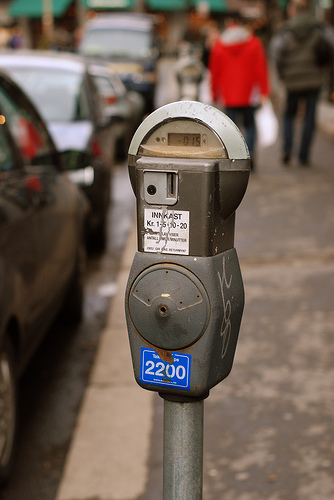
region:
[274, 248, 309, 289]
part of a walkpath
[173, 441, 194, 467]
part of a post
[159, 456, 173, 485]
edge of a post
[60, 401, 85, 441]
edge of a road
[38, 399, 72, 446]
part of a road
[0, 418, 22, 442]
part of a rim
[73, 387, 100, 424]
edge of a line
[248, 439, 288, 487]
part of a walkpath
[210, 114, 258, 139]
part of a metal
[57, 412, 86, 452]
edge of a line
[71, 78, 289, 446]
A parking meter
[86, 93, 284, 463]
A parking meter on a pole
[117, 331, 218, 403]
A blue sticker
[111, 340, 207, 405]
A blue sticker with white numbers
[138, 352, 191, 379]
The number "2200" in white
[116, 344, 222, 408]
white numbers on a blue background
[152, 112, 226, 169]
The number "15"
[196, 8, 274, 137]
A person in a red jacket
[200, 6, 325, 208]
People walking on a sidewalk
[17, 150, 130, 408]
A car parked at a curb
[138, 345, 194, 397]
rectangular blue sticker with the number 2200 on it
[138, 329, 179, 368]
brown rust on metal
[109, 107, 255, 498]
gray parking meter on the side of the street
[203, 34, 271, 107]
bright orange jacket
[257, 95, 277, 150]
white shopping bag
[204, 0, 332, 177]
pedestrians walking down the street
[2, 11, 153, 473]
cars parked on the side of the road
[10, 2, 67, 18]
green awning hanging over a window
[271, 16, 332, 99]
dark, puffy winter jacket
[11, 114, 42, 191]
orange jacket reflected in glass of car window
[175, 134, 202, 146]
The printing on the digital screen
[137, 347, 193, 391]
The blue sign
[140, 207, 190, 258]
The white sign with black writing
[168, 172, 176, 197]
The meter's coin slot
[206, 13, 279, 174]
The person in the red jacket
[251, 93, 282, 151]
The white bag carried by the person in red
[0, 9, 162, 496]
The cars parked at the curb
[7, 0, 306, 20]
The green patio covers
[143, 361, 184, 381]
The number 2200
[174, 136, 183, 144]
The minus sign on the digital sign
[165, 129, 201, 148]
a number display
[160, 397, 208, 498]
a gray metal pole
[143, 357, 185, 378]
white numbers on the sticker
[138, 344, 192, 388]
a blue sticker on the parking meter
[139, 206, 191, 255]
a white sticker on the parking meter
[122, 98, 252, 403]
a gray parking meter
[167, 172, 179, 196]
a black coin slot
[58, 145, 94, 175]
a side view mirror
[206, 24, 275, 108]
a red coat on the person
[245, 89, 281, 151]
a white bag